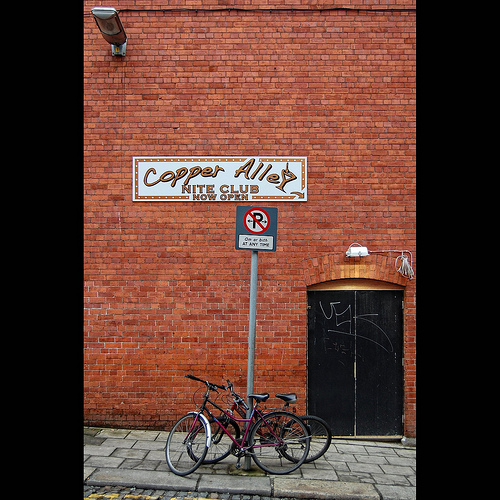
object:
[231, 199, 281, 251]
sign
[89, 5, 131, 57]
security camera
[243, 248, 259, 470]
pole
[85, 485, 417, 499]
street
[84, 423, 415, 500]
sidewalk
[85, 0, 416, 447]
building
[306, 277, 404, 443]
door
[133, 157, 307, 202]
sign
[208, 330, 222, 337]
brick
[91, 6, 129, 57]
light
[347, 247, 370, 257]
light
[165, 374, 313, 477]
bike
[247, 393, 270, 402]
seat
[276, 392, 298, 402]
seat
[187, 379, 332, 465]
bike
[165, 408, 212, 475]
wheel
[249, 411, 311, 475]
wheel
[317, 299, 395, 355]
graffiti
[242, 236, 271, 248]
no parking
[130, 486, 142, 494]
stone